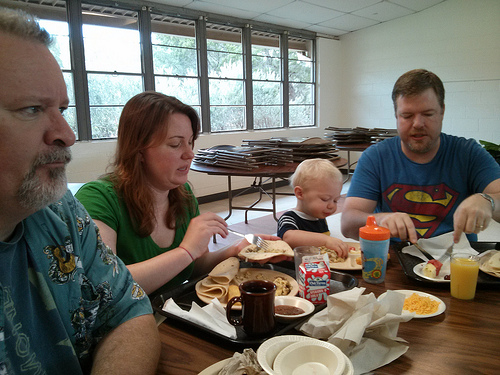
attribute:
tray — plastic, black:
[156, 258, 340, 341]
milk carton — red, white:
[297, 253, 331, 301]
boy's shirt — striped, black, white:
[278, 214, 334, 243]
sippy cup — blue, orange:
[361, 215, 387, 280]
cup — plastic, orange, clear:
[450, 253, 481, 303]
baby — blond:
[278, 165, 340, 245]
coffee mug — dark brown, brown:
[228, 283, 279, 331]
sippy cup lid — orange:
[358, 221, 389, 237]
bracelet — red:
[172, 245, 204, 261]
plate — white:
[261, 336, 335, 374]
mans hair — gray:
[1, 10, 65, 45]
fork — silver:
[219, 226, 284, 247]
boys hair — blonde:
[287, 160, 347, 184]